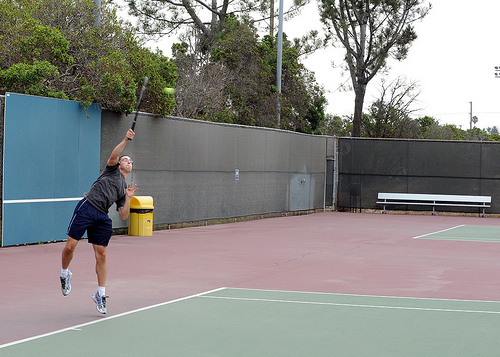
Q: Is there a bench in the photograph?
A: Yes, there is a bench.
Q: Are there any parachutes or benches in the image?
A: Yes, there is a bench.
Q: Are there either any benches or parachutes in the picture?
A: Yes, there is a bench.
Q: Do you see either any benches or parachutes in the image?
A: Yes, there is a bench.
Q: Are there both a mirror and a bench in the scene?
A: No, there is a bench but no mirrors.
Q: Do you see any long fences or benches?
A: Yes, there is a long bench.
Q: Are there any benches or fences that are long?
A: Yes, the bench is long.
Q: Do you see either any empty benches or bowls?
A: Yes, there is an empty bench.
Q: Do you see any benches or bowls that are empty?
A: Yes, the bench is empty.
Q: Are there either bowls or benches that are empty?
A: Yes, the bench is empty.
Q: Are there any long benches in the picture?
A: Yes, there is a long bench.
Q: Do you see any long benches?
A: Yes, there is a long bench.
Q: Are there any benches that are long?
A: Yes, there is a bench that is long.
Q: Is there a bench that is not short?
A: Yes, there is a long bench.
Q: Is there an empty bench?
A: Yes, there is an empty bench.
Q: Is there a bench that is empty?
A: Yes, there is a bench that is empty.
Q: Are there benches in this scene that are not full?
A: Yes, there is a empty bench.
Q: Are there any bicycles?
A: No, there are no bicycles.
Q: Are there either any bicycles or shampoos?
A: No, there are no bicycles or shampoos.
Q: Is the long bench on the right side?
A: Yes, the bench is on the right of the image.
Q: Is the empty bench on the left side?
A: No, the bench is on the right of the image.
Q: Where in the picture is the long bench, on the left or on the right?
A: The bench is on the right of the image.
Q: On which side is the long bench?
A: The bench is on the right of the image.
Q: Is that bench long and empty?
A: Yes, the bench is long and empty.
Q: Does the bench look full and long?
A: No, the bench is long but empty.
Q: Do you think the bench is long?
A: Yes, the bench is long.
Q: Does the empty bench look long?
A: Yes, the bench is long.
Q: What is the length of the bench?
A: The bench is long.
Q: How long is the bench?
A: The bench is long.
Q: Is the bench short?
A: No, the bench is long.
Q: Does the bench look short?
A: No, the bench is long.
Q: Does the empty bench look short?
A: No, the bench is long.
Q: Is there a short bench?
A: No, there is a bench but it is long.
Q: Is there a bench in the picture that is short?
A: No, there is a bench but it is long.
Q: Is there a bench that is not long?
A: No, there is a bench but it is long.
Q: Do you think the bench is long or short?
A: The bench is long.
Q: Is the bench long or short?
A: The bench is long.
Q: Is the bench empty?
A: Yes, the bench is empty.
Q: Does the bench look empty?
A: Yes, the bench is empty.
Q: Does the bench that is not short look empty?
A: Yes, the bench is empty.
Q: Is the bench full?
A: No, the bench is empty.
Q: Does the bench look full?
A: No, the bench is empty.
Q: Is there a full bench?
A: No, there is a bench but it is empty.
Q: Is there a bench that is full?
A: No, there is a bench but it is empty.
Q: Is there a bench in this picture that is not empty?
A: No, there is a bench but it is empty.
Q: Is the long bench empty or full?
A: The bench is empty.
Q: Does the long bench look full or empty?
A: The bench is empty.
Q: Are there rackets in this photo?
A: Yes, there is a racket.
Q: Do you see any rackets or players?
A: Yes, there is a racket.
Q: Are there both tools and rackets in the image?
A: No, there is a racket but no tools.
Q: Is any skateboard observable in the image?
A: No, there are no skateboards.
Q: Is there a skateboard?
A: No, there are no skateboards.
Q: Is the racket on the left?
A: Yes, the racket is on the left of the image.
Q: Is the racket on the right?
A: No, the racket is on the left of the image.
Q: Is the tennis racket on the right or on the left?
A: The tennis racket is on the left of the image.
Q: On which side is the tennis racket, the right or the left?
A: The tennis racket is on the left of the image.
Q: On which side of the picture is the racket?
A: The racket is on the left of the image.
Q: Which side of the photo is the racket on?
A: The racket is on the left of the image.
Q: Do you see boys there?
A: No, there are no boys.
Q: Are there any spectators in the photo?
A: No, there are no spectators.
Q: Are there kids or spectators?
A: No, there are no spectators or kids.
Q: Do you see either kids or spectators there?
A: No, there are no spectators or kids.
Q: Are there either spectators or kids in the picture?
A: No, there are no spectators or kids.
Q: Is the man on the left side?
A: Yes, the man is on the left of the image.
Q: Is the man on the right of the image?
A: No, the man is on the left of the image.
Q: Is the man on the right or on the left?
A: The man is on the left of the image.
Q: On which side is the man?
A: The man is on the left of the image.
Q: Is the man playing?
A: Yes, the man is playing.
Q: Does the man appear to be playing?
A: Yes, the man is playing.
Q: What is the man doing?
A: The man is playing.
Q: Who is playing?
A: The man is playing.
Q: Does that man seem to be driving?
A: No, the man is playing.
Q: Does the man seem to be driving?
A: No, the man is playing.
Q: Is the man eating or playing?
A: The man is playing.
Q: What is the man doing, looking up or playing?
A: The man is playing.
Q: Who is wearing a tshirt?
A: The man is wearing a tshirt.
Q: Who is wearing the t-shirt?
A: The man is wearing a tshirt.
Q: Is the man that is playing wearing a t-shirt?
A: Yes, the man is wearing a t-shirt.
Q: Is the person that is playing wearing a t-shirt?
A: Yes, the man is wearing a t-shirt.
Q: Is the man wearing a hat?
A: No, the man is wearing a t-shirt.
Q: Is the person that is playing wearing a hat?
A: No, the man is wearing a t-shirt.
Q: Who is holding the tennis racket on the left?
A: The man is holding the tennis racket.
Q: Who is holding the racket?
A: The man is holding the tennis racket.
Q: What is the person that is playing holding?
A: The man is holding the racket.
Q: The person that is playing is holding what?
A: The man is holding the racket.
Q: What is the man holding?
A: The man is holding the racket.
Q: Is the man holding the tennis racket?
A: Yes, the man is holding the tennis racket.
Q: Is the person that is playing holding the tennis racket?
A: Yes, the man is holding the tennis racket.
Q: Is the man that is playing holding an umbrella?
A: No, the man is holding the tennis racket.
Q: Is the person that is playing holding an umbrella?
A: No, the man is holding the tennis racket.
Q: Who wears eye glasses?
A: The man wears eye glasses.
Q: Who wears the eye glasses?
A: The man wears eye glasses.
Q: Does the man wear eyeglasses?
A: Yes, the man wears eyeglasses.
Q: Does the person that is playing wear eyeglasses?
A: Yes, the man wears eyeglasses.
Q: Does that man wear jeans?
A: No, the man wears eyeglasses.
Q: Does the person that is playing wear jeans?
A: No, the man wears eyeglasses.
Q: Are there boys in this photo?
A: No, there are no boys.